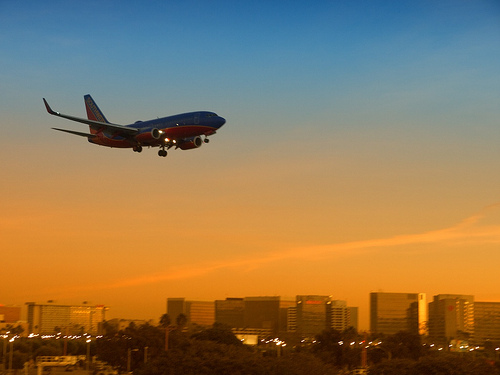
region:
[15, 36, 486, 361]
plane flying low near city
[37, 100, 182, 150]
lights on wing and body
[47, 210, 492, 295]
long streaky cloud over sky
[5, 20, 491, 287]
sky changing from blue to orange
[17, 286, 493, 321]
flat tops of tall buildings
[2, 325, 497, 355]
white lights from lampposts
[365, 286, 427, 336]
building reflecting another building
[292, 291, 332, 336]
red glowing sign on top of building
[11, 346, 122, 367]
white structure with railing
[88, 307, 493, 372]
trees in front of buildings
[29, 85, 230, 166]
airplane with red bottom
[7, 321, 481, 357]
lights along bottom of cityscape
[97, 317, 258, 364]
trees along the cityscape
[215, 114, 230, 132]
nose of the airplane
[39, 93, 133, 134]
long wing of airplane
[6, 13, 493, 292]
two tone sky above city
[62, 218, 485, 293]
cloud running the lenght of cityscape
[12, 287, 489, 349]
buildings in the city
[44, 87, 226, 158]
plane flying above city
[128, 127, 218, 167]
three sets of wheels on plane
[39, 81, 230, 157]
plane flying across the sky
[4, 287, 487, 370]
cityscape in the background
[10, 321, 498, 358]
lights along the roadway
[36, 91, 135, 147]
wings of the airplane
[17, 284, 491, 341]
buildings along cityscape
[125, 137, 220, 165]
wheels on the airplane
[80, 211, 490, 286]
long cloud in the sky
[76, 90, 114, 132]
tail fin of airplane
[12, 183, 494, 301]
yellow part of sky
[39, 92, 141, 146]
The left side wing of the plane.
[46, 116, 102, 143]
The left side wing near the tail of the plane.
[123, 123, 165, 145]
The engine under the left wing.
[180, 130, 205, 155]
The engine under the right wing.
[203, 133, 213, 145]
The front wheel of the plane.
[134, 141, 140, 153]
The left back wheel.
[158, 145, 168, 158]
The right back wheel.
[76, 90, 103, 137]
The tail of the plane.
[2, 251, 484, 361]
The buildings of the city.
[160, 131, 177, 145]
The lights under the body of the plane.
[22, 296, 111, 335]
building on the horizon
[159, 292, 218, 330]
building on the horizon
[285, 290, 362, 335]
building on the horizon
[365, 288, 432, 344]
building on the horizon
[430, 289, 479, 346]
building on the horizon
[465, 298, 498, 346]
building on the horizon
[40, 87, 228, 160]
airplane in the sky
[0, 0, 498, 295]
blue sky with some clouds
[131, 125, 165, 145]
engine on an airplane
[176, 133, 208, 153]
engine on an airplane